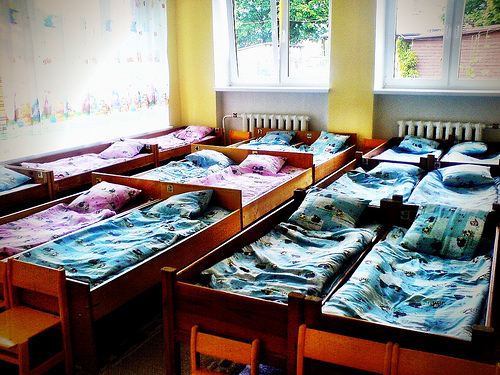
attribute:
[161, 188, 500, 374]
beds — close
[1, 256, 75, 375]
chair — wooden, in front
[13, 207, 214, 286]
sheet — blue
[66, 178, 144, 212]
pillow — pink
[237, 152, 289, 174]
pillow — pink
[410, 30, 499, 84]
wall — brick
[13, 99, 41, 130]
drawing — animals character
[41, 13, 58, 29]
drawing — animals character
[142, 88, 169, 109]
drawing — animals character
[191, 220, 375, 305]
sheet — blue, ruffled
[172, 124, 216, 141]
pillow — pink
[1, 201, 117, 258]
sheet — pink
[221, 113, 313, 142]
radiator — white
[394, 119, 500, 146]
radiator — white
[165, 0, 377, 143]
wall — yellow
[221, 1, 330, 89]
window — in back, at left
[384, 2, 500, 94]
window — in back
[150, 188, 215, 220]
pillow — blue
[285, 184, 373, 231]
pillow — blue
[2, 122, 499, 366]
group — small beds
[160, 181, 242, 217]
headboard — wooden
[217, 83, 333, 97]
window sill — white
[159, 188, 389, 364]
bed — sunken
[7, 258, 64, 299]
back rest — wooden